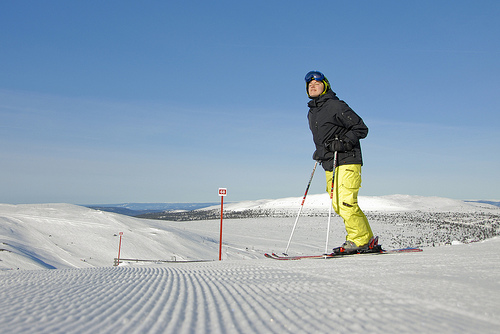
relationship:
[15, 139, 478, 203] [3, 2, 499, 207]
clouds in sky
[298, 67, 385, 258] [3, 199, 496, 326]
man on snow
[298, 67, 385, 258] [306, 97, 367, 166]
man wearing jacket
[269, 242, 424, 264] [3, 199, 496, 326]
skis on snow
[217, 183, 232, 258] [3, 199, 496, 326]
sign in snow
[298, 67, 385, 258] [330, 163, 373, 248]
man wearing pants